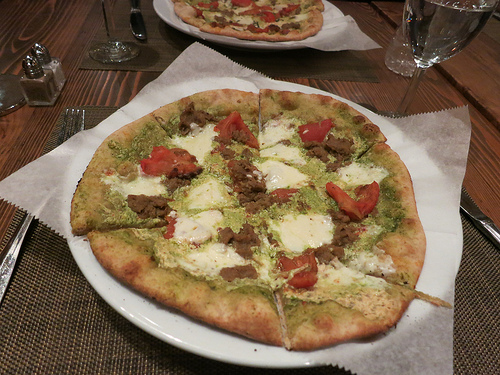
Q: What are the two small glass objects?
A: Salt and pepper shakers.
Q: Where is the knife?
A: Right of the plate.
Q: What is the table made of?
A: Wood.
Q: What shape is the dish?
A: Round.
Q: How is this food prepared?
A: Baked.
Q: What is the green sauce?
A: Pesto.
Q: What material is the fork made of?
A: Stainless steel.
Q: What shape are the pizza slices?
A: Triangles.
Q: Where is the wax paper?
A: Under the pizzas.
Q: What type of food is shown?
A: Pizza.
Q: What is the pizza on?
A: Paper.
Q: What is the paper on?
A: Plate.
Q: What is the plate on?
A: Table.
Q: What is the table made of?
A: Wood.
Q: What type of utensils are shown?
A: Fork and knife.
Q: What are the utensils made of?
A: Metal.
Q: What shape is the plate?
A: Round.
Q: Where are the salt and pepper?
A: Left side.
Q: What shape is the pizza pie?
A: Round.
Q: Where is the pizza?
A: On a plate.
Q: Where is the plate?
A: On a placemat.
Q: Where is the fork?
A: To the left of the plate.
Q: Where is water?
A: In a glass.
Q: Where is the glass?
A: On the table.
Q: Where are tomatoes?
A: On the pizza.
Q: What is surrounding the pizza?
A: A crust.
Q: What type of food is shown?
A: Pizza.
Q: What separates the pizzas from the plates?
A: Paper.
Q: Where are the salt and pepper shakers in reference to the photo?
A: Top left.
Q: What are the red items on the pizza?
A: Tomatoes.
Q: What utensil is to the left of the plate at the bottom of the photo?
A: Fork.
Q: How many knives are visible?
A: Two.